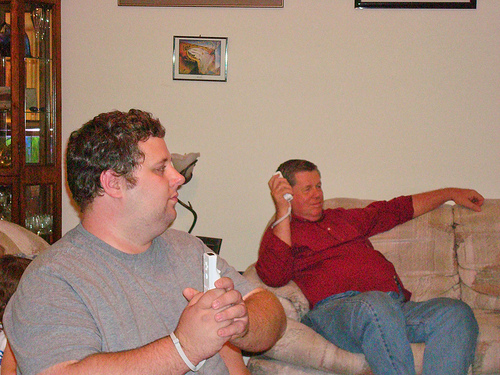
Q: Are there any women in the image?
A: No, there are no women.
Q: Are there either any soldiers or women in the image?
A: No, there are no women or soldiers.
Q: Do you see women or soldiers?
A: No, there are no women or soldiers.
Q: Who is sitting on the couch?
A: The man is sitting on the couch.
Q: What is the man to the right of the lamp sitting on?
A: The man is sitting on the couch.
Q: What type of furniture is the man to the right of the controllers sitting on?
A: The man is sitting on the couch.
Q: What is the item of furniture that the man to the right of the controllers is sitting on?
A: The piece of furniture is a couch.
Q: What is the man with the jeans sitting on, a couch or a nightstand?
A: The man is sitting on a couch.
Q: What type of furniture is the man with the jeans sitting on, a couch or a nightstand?
A: The man is sitting on a couch.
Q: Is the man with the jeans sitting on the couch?
A: Yes, the man is sitting on the couch.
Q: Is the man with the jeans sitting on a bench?
A: No, the man is sitting on the couch.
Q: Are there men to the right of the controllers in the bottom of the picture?
A: Yes, there is a man to the right of the controllers.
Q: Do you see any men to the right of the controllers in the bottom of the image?
A: Yes, there is a man to the right of the controllers.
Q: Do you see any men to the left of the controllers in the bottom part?
A: No, the man is to the right of the controllers.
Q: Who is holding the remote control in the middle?
A: The man is holding the remote control.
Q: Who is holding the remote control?
A: The man is holding the remote control.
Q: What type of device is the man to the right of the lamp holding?
A: The man is holding the remote control.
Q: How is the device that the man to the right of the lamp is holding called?
A: The device is a remote control.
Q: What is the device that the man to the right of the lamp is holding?
A: The device is a remote control.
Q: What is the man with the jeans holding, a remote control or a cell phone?
A: The man is holding a remote control.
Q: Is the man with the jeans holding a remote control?
A: Yes, the man is holding a remote control.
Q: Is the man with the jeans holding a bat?
A: No, the man is holding a remote control.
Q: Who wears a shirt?
A: The man wears a shirt.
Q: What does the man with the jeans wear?
A: The man wears a shirt.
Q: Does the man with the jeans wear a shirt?
A: Yes, the man wears a shirt.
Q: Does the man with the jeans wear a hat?
A: No, the man wears a shirt.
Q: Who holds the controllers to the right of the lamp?
A: The man holds the controllers.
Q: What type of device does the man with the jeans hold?
A: The man holds the controllers.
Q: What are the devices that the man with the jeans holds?
A: The devices are controllers.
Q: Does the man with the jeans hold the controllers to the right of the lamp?
A: Yes, the man holds the controllers.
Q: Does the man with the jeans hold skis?
A: No, the man holds the controllers.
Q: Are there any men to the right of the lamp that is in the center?
A: Yes, there is a man to the right of the lamp.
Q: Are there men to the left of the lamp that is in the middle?
A: No, the man is to the right of the lamp.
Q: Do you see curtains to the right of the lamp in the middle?
A: No, there is a man to the right of the lamp.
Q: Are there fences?
A: No, there are no fences.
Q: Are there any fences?
A: No, there are no fences.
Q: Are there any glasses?
A: No, there are no glasses.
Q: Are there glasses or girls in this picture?
A: No, there are no glasses or girls.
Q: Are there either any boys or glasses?
A: No, there are no glasses or boys.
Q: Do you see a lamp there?
A: Yes, there is a lamp.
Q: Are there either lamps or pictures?
A: Yes, there is a lamp.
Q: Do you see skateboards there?
A: No, there are no skateboards.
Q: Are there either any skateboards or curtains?
A: No, there are no skateboards or curtains.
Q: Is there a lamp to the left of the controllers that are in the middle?
A: Yes, there is a lamp to the left of the controllers.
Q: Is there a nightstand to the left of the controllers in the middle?
A: No, there is a lamp to the left of the controllers.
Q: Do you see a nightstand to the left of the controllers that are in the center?
A: No, there is a lamp to the left of the controllers.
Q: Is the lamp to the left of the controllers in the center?
A: Yes, the lamp is to the left of the controllers.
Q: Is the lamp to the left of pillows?
A: No, the lamp is to the left of the controllers.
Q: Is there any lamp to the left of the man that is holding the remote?
A: Yes, there is a lamp to the left of the man.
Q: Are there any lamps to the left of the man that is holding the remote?
A: Yes, there is a lamp to the left of the man.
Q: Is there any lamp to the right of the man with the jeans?
A: No, the lamp is to the left of the man.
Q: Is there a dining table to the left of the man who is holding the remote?
A: No, there is a lamp to the left of the man.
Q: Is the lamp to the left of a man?
A: Yes, the lamp is to the left of a man.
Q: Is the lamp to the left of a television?
A: No, the lamp is to the left of a man.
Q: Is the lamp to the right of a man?
A: No, the lamp is to the left of a man.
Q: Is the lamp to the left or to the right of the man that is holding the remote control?
A: The lamp is to the left of the man.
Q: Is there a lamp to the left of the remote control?
A: Yes, there is a lamp to the left of the remote control.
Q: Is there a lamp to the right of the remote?
A: No, the lamp is to the left of the remote.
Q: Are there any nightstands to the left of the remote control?
A: No, there is a lamp to the left of the remote control.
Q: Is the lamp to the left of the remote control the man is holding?
A: Yes, the lamp is to the left of the remote control.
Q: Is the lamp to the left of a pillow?
A: No, the lamp is to the left of the remote control.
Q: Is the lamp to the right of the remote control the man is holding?
A: No, the lamp is to the left of the remote.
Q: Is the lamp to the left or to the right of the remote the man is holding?
A: The lamp is to the left of the remote.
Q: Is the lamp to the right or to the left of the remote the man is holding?
A: The lamp is to the left of the remote.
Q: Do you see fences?
A: No, there are no fences.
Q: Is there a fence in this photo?
A: No, there are no fences.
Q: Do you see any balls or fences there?
A: No, there are no fences or balls.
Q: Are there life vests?
A: No, there are no life vests.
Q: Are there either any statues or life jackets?
A: No, there are no life jackets or statues.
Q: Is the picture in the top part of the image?
A: Yes, the picture is in the top of the image.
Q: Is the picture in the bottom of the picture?
A: No, the picture is in the top of the image.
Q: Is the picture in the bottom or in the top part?
A: The picture is in the top of the image.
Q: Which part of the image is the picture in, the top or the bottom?
A: The picture is in the top of the image.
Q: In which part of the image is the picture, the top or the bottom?
A: The picture is in the top of the image.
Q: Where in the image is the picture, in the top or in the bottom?
A: The picture is in the top of the image.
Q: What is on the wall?
A: The picture is on the wall.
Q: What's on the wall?
A: The picture is on the wall.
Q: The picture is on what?
A: The picture is on the wall.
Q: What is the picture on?
A: The picture is on the wall.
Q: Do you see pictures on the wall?
A: Yes, there is a picture on the wall.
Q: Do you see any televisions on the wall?
A: No, there is a picture on the wall.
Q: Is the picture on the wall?
A: Yes, the picture is on the wall.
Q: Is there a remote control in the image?
A: Yes, there is a remote control.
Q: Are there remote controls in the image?
A: Yes, there is a remote control.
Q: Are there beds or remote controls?
A: Yes, there is a remote control.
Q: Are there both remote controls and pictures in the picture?
A: Yes, there are both a remote control and a picture.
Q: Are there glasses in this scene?
A: No, there are no glasses.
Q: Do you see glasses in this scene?
A: No, there are no glasses.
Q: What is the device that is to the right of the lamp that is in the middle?
A: The device is a remote control.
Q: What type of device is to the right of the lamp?
A: The device is a remote control.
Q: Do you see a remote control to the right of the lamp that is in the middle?
A: Yes, there is a remote control to the right of the lamp.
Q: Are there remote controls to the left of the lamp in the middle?
A: No, the remote control is to the right of the lamp.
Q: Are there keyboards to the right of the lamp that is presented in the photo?
A: No, there is a remote control to the right of the lamp.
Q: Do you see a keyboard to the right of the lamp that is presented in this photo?
A: No, there is a remote control to the right of the lamp.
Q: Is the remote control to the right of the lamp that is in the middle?
A: Yes, the remote control is to the right of the lamp.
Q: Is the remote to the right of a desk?
A: No, the remote is to the right of the lamp.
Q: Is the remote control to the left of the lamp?
A: No, the remote control is to the right of the lamp.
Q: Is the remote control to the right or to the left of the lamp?
A: The remote control is to the right of the lamp.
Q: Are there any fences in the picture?
A: No, there are no fences.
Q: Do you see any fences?
A: No, there are no fences.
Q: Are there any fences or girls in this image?
A: No, there are no fences or girls.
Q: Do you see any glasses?
A: No, there are no glasses.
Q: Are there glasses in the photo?
A: No, there are no glasses.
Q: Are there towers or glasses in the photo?
A: No, there are no glasses or towers.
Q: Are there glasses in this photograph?
A: No, there are no glasses.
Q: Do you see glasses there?
A: No, there are no glasses.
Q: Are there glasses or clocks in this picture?
A: No, there are no glasses or clocks.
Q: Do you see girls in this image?
A: No, there are no girls.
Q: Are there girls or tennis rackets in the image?
A: No, there are no girls or tennis rackets.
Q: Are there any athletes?
A: No, there are no athletes.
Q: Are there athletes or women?
A: No, there are no athletes or women.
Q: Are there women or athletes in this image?
A: No, there are no athletes or women.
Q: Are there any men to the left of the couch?
A: Yes, there is a man to the left of the couch.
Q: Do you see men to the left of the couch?
A: Yes, there is a man to the left of the couch.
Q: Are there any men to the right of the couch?
A: No, the man is to the left of the couch.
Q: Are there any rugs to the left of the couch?
A: No, there is a man to the left of the couch.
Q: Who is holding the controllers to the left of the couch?
A: The man is holding the controllers.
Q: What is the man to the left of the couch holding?
A: The man is holding the controllers.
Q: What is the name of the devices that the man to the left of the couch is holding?
A: The devices are controllers.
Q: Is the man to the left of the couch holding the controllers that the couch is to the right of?
A: Yes, the man is holding the controllers.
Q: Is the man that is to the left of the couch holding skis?
A: No, the man is holding the controllers.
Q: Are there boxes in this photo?
A: No, there are no boxes.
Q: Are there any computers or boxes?
A: No, there are no boxes or computers.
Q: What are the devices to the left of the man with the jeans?
A: The devices are controllers.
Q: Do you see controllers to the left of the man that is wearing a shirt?
A: Yes, there are controllers to the left of the man.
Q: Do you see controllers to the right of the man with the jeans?
A: No, the controllers are to the left of the man.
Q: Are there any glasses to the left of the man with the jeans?
A: No, there are controllers to the left of the man.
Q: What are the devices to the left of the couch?
A: The devices are controllers.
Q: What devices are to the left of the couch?
A: The devices are controllers.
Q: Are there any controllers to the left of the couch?
A: Yes, there are controllers to the left of the couch.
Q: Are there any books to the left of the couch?
A: No, there are controllers to the left of the couch.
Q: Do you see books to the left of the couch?
A: No, there are controllers to the left of the couch.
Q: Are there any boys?
A: No, there are no boys.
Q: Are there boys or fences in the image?
A: No, there are no boys or fences.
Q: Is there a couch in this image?
A: Yes, there is a couch.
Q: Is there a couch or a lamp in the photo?
A: Yes, there is a couch.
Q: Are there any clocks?
A: No, there are no clocks.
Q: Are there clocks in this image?
A: No, there are no clocks.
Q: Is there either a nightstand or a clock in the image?
A: No, there are no clocks or nightstands.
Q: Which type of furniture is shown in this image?
A: The furniture is a couch.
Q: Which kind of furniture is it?
A: The piece of furniture is a couch.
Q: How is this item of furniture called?
A: This is a couch.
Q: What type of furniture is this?
A: This is a couch.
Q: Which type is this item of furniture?
A: This is a couch.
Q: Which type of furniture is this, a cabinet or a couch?
A: This is a couch.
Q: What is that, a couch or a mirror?
A: That is a couch.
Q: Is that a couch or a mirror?
A: That is a couch.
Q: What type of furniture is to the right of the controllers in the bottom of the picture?
A: The piece of furniture is a couch.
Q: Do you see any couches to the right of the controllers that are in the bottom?
A: Yes, there is a couch to the right of the controllers.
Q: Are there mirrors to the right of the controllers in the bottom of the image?
A: No, there is a couch to the right of the controllers.